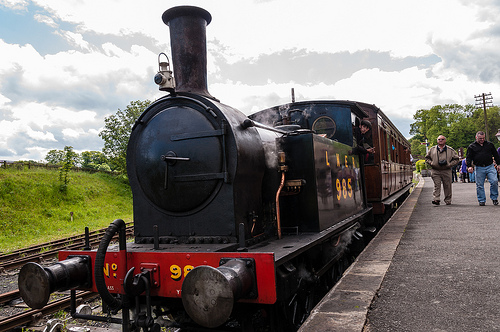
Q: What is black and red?
A: Train.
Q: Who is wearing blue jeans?
A: Man on right.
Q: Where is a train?
A: On train tracks.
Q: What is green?
A: Grass.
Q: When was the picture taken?
A: Daytime.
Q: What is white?
A: Clouds.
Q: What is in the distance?
A: Trees.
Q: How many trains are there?
A: One.